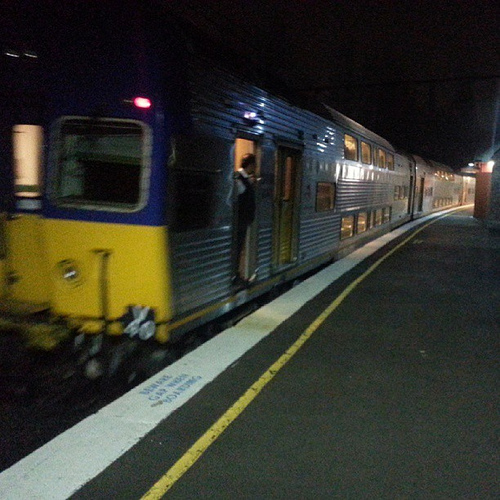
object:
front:
[0, 29, 163, 337]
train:
[0, 83, 478, 381]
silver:
[243, 117, 337, 143]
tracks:
[28, 360, 91, 418]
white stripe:
[0, 204, 478, 499]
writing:
[134, 366, 208, 414]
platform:
[0, 211, 500, 500]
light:
[129, 96, 153, 110]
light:
[482, 160, 496, 177]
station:
[471, 142, 500, 225]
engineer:
[230, 151, 259, 287]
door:
[233, 128, 256, 288]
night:
[0, 0, 497, 499]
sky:
[0, 1, 500, 168]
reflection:
[336, 163, 376, 182]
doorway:
[234, 133, 261, 289]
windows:
[341, 134, 359, 162]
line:
[138, 217, 440, 499]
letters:
[139, 319, 155, 341]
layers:
[336, 163, 396, 215]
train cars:
[0, 57, 415, 389]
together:
[403, 161, 423, 221]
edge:
[245, 263, 334, 318]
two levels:
[336, 127, 364, 247]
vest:
[234, 175, 259, 224]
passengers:
[346, 145, 356, 159]